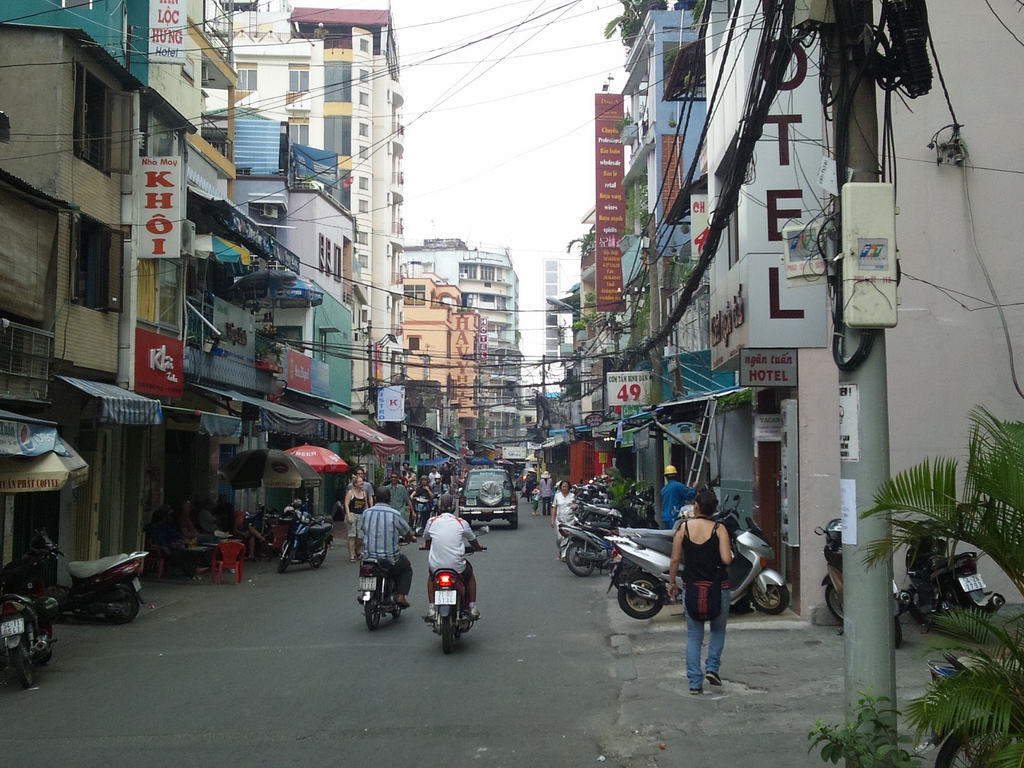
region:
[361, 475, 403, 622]
man riding on motorbike in street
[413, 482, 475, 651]
man riding on motorbike in street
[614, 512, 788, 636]
motorcycle parked on side of street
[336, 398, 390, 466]
red awning on side of building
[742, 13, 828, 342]
white and red motel sign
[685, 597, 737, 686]
blue denim jeans on woman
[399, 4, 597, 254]
cloudy white sky above street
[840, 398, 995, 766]
green palm on side of road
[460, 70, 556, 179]
a view of sky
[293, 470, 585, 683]
a bikes in road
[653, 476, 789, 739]
a girl in road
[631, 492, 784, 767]
a girl near buildiing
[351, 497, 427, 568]
a man in bike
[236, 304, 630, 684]
a view of traffic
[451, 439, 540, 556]
a van in road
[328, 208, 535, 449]
a view of building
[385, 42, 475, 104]
a view of wire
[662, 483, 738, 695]
woman wearing black tanktop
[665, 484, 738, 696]
woman wearing blue jeans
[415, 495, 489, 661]
man in white shirt riding motorcycle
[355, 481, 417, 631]
man riding a motorcycle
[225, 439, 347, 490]
two open umbrellas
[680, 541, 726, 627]
black and red bag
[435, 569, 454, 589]
bright red lit brake light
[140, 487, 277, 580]
people sitting in front of building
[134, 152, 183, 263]
white sign with red letters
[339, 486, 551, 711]
two people on mopeds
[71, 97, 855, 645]
a busy narrow street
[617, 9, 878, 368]
white sign for a hotel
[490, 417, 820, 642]
row of motorcycles and mopeds parked on the street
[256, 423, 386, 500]
red umbrella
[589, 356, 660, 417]
white sign with the number 49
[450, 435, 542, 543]
green car driving down the street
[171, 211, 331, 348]
several patio umbrellas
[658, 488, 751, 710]
woman walking on road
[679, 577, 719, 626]
woman's bag hanging at back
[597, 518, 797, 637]
motorcyle parked at building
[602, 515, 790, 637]
parked motorcycle is silver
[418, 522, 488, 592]
the white shirt of a man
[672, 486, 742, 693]
Woman walking on the side of the road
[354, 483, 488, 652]
Two man on motorcycles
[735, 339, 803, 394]
White and red hotel sign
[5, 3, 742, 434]
Black cables hanging between buildings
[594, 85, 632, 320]
Red signage on the side of a bilding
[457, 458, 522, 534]
Car in the middle of the road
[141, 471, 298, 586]
People sitting in chairs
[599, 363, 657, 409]
Number 49 on a sign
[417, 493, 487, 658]
man is riding a motorcycle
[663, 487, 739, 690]
lady is walking beside the street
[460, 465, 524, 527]
car is in the street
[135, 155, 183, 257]
sign is attached to building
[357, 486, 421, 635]
man is riding motorcycle in the street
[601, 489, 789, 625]
motorcycle is in front of the building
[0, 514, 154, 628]
motorcycle is in front of the building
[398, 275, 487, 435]
building is in the distance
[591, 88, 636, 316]
sign is attached to the building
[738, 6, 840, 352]
sign is on the side of the building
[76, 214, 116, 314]
glass window on building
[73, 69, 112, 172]
glass window on building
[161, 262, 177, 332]
glass window on building